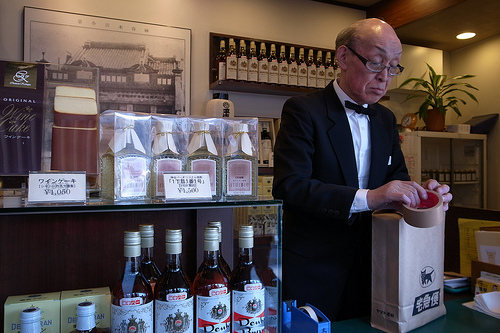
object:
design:
[410, 287, 443, 318]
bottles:
[110, 226, 158, 332]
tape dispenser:
[287, 302, 334, 332]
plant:
[395, 59, 481, 121]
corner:
[435, 48, 461, 132]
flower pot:
[420, 107, 447, 133]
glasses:
[343, 42, 406, 76]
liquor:
[97, 112, 154, 204]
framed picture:
[20, 5, 197, 118]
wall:
[0, 2, 368, 122]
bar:
[0, 0, 500, 332]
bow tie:
[343, 98, 372, 116]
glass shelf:
[0, 196, 285, 211]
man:
[269, 16, 455, 327]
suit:
[272, 77, 413, 321]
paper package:
[368, 209, 446, 331]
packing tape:
[400, 188, 446, 230]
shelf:
[208, 77, 319, 98]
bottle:
[100, 111, 156, 207]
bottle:
[223, 37, 239, 83]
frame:
[340, 43, 406, 77]